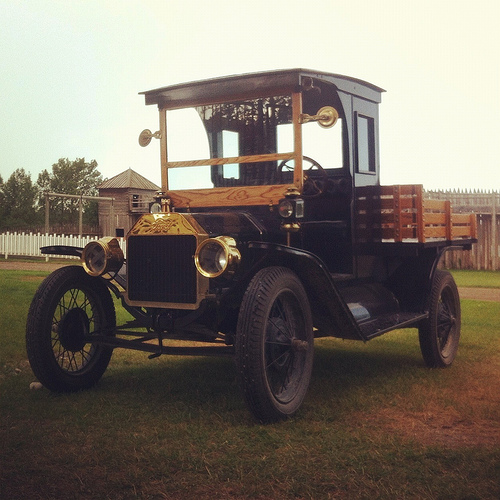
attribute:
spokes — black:
[260, 294, 317, 407]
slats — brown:
[422, 212, 476, 227]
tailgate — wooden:
[377, 181, 482, 244]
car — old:
[26, 70, 468, 391]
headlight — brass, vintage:
[161, 220, 263, 280]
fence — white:
[3, 234, 39, 259]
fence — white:
[52, 231, 80, 244]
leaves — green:
[56, 155, 98, 193]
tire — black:
[233, 263, 314, 421]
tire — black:
[418, 267, 461, 369]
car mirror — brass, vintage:
[284, 93, 349, 151]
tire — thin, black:
[423, 261, 465, 365]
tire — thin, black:
[236, 261, 319, 422]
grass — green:
[3, 257, 498, 499]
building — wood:
[95, 168, 157, 235]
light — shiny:
[81, 235, 113, 277]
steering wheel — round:
[274, 140, 313, 214]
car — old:
[71, 73, 446, 379]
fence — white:
[0, 225, 127, 260]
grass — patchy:
[114, 421, 234, 486]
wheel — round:
[221, 259, 336, 423]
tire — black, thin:
[26, 265, 118, 387]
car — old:
[36, 32, 474, 414]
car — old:
[42, 54, 497, 383]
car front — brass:
[80, 198, 245, 310]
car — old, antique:
[24, 60, 475, 422]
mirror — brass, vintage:
[303, 104, 340, 129]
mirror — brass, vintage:
[134, 122, 163, 147]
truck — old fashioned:
[25, 68, 483, 421]